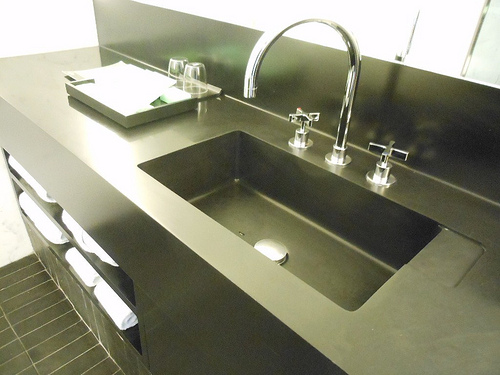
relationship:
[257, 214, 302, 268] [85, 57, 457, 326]
drain in sink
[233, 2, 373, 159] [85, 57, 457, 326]
faucet for sink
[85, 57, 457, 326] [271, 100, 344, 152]
sink has handle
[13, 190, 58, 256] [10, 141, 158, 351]
towel on shelves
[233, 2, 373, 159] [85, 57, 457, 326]
faucet on sink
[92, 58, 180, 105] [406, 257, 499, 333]
napkin on counter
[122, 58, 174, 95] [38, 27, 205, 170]
napkin on table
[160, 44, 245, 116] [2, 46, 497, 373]
glass on counter